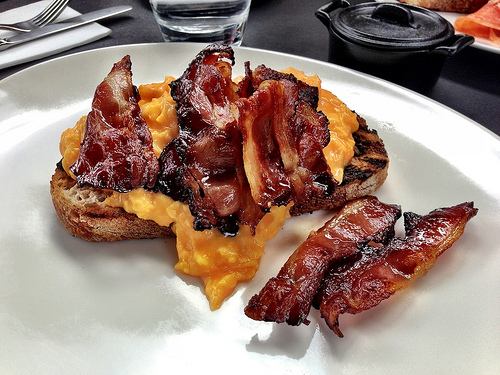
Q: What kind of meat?
A: Bacon.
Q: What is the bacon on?
A: Cheese.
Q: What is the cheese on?
A: Bread.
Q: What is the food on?
A: Plate.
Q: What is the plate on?
A: Table.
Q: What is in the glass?
A: Water.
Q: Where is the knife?
A: On the napkin.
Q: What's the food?
A: Bacon.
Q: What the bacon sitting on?
A: White plate.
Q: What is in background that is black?
A: Cup with lid.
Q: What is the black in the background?
A: Mini black pot.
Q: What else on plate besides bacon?
A: Cheese.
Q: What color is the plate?
A: White.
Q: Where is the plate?
A: On the table.